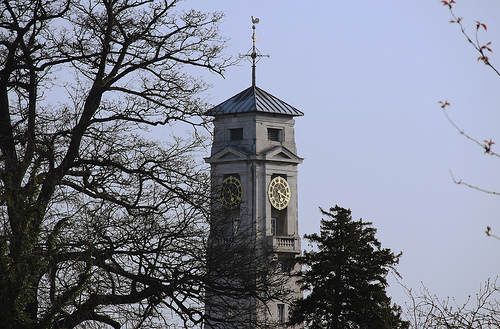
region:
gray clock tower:
[206, 9, 321, 327]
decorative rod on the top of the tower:
[239, 16, 271, 89]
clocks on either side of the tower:
[206, 164, 297, 231]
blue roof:
[195, 81, 297, 121]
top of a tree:
[286, 191, 413, 324]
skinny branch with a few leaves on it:
[431, 90, 499, 152]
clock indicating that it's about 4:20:
[261, 168, 303, 216]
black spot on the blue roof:
[231, 81, 274, 102]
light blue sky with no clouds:
[274, 7, 499, 282]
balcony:
[269, 230, 300, 254]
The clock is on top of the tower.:
[258, 167, 295, 217]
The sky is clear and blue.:
[235, 28, 448, 200]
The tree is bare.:
[13, 15, 188, 300]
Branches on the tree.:
[36, 63, 171, 270]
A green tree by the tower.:
[307, 193, 407, 328]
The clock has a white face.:
[252, 168, 308, 220]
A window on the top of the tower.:
[228, 115, 254, 150]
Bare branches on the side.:
[426, 111, 496, 219]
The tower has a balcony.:
[258, 219, 305, 252]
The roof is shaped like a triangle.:
[212, 79, 307, 116]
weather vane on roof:
[218, 7, 287, 90]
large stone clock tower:
[189, 7, 324, 325]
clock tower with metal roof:
[194, 10, 319, 325]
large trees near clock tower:
[3, 1, 422, 326]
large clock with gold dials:
[260, 165, 302, 221]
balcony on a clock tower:
[254, 139, 311, 268]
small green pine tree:
[281, 200, 422, 327]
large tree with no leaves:
[5, 2, 203, 325]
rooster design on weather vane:
[228, 5, 280, 91]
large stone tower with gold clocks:
[191, 10, 322, 327]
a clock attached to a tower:
[265, 170, 301, 218]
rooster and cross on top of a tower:
[240, 12, 269, 77]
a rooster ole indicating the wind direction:
[222, 30, 272, 75]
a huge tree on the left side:
[0, 4, 215, 321]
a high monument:
[205, 15, 301, 326]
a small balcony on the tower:
[268, 211, 310, 254]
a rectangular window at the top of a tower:
[267, 120, 290, 140]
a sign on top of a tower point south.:
[234, 36, 275, 75]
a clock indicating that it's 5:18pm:
[262, 172, 309, 227]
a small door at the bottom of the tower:
[272, 302, 291, 326]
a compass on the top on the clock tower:
[217, 4, 294, 103]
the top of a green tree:
[278, 165, 415, 325]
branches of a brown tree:
[10, 12, 242, 325]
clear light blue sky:
[331, 62, 388, 150]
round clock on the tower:
[263, 160, 303, 214]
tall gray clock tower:
[173, 5, 328, 325]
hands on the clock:
[272, 185, 293, 204]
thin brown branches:
[439, 1, 493, 269]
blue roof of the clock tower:
[208, 74, 320, 134]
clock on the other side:
[202, 169, 260, 219]